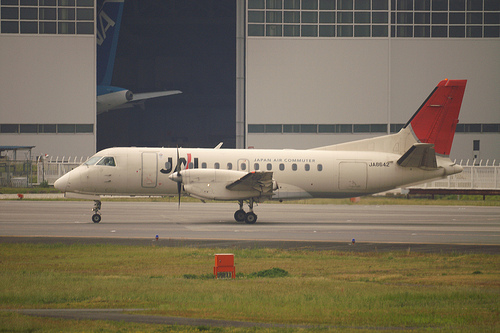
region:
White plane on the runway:
[56, 78, 471, 224]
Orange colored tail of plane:
[408, 75, 465, 157]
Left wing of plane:
[226, 169, 273, 196]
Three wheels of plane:
[91, 210, 268, 225]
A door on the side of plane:
[142, 153, 157, 188]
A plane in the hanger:
[100, 69, 183, 117]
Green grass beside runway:
[1, 237, 498, 331]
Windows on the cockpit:
[83, 155, 116, 166]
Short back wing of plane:
[395, 138, 442, 168]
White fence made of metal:
[453, 158, 498, 195]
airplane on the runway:
[51, 78, 472, 222]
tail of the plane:
[398, 67, 488, 177]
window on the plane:
[314, 163, 329, 179]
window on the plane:
[302, 160, 313, 179]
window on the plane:
[290, 161, 300, 176]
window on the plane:
[277, 159, 285, 174]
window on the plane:
[262, 160, 279, 178]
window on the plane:
[266, 160, 276, 173]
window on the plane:
[238, 161, 250, 171]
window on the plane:
[225, 162, 237, 172]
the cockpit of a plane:
[76, 152, 121, 172]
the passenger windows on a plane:
[183, 159, 330, 179]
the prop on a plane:
[170, 143, 187, 205]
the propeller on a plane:
[165, 145, 183, 207]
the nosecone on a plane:
[52, 175, 67, 192]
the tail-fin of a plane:
[401, 70, 473, 160]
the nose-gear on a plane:
[80, 193, 105, 223]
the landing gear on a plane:
[234, 198, 258, 224]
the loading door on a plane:
[136, 148, 162, 192]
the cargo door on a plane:
[333, 154, 369, 192]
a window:
[94, 157, 119, 166]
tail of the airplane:
[407, 77, 462, 149]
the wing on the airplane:
[231, 168, 284, 190]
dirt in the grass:
[323, 265, 403, 280]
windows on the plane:
[254, 163, 334, 170]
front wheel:
[87, 210, 102, 227]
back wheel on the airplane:
[227, 206, 258, 221]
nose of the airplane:
[50, 175, 68, 192]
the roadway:
[320, 204, 455, 243]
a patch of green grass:
[254, 262, 284, 278]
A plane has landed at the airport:
[0, 26, 486, 306]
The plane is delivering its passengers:
[1, 25, 479, 315]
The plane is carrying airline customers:
[2, 15, 490, 330]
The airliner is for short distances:
[1, 21, 491, 311]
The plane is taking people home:
[5, 30, 496, 310]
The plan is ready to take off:
[10, 45, 485, 275]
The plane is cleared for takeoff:
[5, 55, 490, 295]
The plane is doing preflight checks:
[5, 33, 495, 300]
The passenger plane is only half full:
[0, 62, 498, 305]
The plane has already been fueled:
[5, 43, 499, 305]